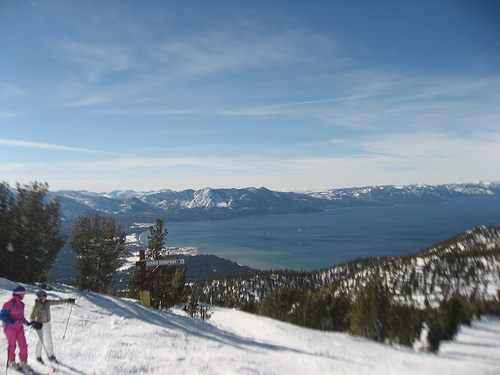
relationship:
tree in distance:
[145, 219, 174, 259] [79, 184, 264, 251]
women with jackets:
[2, 283, 67, 361] [8, 297, 66, 329]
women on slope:
[2, 283, 67, 361] [68, 286, 442, 374]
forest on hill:
[289, 269, 461, 335] [242, 242, 499, 347]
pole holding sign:
[137, 271, 155, 307] [136, 254, 198, 273]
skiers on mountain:
[2, 283, 67, 361] [16, 208, 499, 371]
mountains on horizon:
[74, 183, 491, 210] [8, 171, 493, 224]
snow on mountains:
[89, 184, 296, 203] [74, 183, 491, 210]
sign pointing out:
[136, 254, 198, 273] [198, 185, 489, 296]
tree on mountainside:
[145, 219, 174, 259] [126, 221, 424, 373]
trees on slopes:
[275, 275, 402, 341] [174, 242, 476, 350]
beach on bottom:
[183, 243, 273, 281] [108, 223, 267, 287]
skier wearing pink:
[1, 286, 39, 371] [1, 300, 28, 355]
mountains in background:
[74, 183, 491, 210] [36, 119, 433, 271]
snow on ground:
[123, 319, 224, 350] [68, 286, 442, 374]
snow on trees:
[360, 267, 413, 300] [275, 275, 402, 341]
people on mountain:
[2, 283, 67, 361] [16, 208, 499, 371]